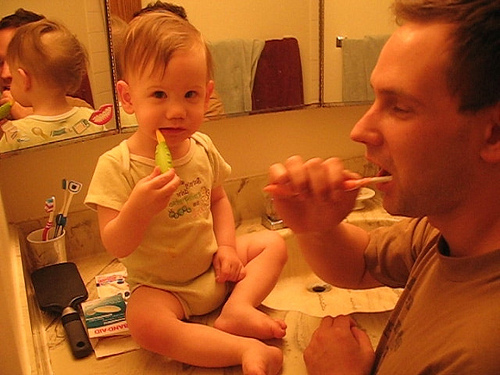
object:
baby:
[83, 9, 286, 374]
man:
[264, 2, 498, 374]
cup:
[26, 227, 67, 268]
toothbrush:
[41, 196, 57, 241]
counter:
[24, 182, 422, 374]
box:
[75, 292, 141, 360]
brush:
[29, 260, 95, 360]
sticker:
[88, 101, 114, 126]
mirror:
[100, 1, 323, 135]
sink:
[252, 221, 404, 318]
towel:
[248, 36, 306, 119]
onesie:
[81, 131, 235, 321]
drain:
[306, 282, 330, 294]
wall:
[1, 102, 377, 268]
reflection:
[0, 20, 107, 155]